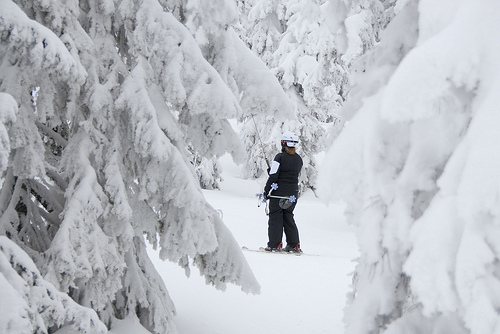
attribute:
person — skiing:
[262, 132, 306, 258]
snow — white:
[211, 188, 350, 330]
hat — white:
[279, 131, 302, 142]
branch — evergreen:
[119, 65, 260, 293]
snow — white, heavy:
[123, 68, 205, 234]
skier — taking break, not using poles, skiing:
[257, 132, 310, 258]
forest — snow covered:
[3, 16, 496, 331]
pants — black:
[266, 194, 302, 248]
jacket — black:
[264, 153, 309, 197]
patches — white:
[268, 161, 280, 174]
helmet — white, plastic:
[279, 129, 302, 143]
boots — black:
[267, 239, 303, 252]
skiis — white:
[242, 240, 323, 260]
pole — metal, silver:
[247, 108, 274, 176]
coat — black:
[263, 154, 304, 197]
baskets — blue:
[271, 182, 295, 201]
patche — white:
[267, 158, 283, 177]